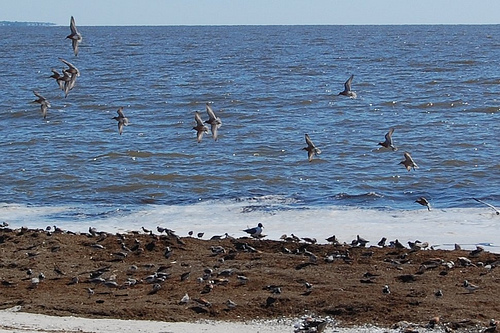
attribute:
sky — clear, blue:
[173, 0, 402, 20]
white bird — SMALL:
[137, 221, 154, 236]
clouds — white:
[124, 5, 307, 21]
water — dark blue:
[1, 13, 499, 256]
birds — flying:
[2, 10, 441, 199]